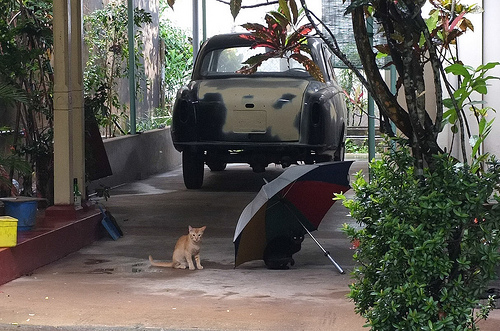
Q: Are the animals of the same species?
A: Yes, all the animals are cats.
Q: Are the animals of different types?
A: No, all the animals are cats.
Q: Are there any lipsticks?
A: No, there are no lipsticks.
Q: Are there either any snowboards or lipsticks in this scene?
A: No, there are no lipsticks or snowboards.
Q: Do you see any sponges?
A: No, there are no sponges.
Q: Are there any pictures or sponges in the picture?
A: No, there are no sponges or pictures.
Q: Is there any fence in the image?
A: No, there are no fences.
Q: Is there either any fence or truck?
A: No, there are no fences or trucks.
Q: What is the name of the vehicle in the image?
A: The vehicle is a car.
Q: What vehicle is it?
A: The vehicle is a car.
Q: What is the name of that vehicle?
A: This is a car.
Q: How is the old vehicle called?
A: The vehicle is a car.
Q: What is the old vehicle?
A: The vehicle is a car.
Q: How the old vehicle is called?
A: The vehicle is a car.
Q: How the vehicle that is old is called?
A: The vehicle is a car.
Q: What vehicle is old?
A: The vehicle is a car.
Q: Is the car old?
A: Yes, the car is old.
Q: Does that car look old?
A: Yes, the car is old.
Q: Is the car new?
A: No, the car is old.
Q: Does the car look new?
A: No, the car is old.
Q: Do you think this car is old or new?
A: The car is old.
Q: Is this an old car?
A: Yes, this is an old car.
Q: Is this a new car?
A: No, this is an old car.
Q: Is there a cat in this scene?
A: Yes, there is a cat.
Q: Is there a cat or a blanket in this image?
A: Yes, there is a cat.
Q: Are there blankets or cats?
A: Yes, there is a cat.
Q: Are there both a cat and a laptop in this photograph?
A: No, there is a cat but no laptops.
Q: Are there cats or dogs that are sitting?
A: Yes, the cat is sitting.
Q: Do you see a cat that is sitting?
A: Yes, there is a cat that is sitting.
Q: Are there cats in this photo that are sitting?
A: Yes, there is a cat that is sitting.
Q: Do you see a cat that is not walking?
A: Yes, there is a cat that is sitting .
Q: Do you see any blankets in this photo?
A: No, there are no blankets.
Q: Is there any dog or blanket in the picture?
A: No, there are no blankets or dogs.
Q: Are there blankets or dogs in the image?
A: No, there are no blankets or dogs.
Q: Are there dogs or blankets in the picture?
A: No, there are no blankets or dogs.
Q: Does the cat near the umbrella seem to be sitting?
A: Yes, the cat is sitting.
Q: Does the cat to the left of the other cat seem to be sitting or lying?
A: The cat is sitting.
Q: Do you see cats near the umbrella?
A: Yes, there is a cat near the umbrella.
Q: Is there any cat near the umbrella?
A: Yes, there is a cat near the umbrella.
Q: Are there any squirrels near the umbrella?
A: No, there is a cat near the umbrella.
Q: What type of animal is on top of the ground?
A: The animal is a cat.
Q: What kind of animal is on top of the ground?
A: The animal is a cat.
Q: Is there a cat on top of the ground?
A: Yes, there is a cat on top of the ground.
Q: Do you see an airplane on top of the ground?
A: No, there is a cat on top of the ground.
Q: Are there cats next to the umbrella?
A: Yes, there is a cat next to the umbrella.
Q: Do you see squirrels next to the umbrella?
A: No, there is a cat next to the umbrella.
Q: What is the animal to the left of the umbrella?
A: The animal is a cat.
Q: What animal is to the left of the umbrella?
A: The animal is a cat.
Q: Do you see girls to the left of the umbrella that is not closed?
A: No, there is a cat to the left of the umbrella.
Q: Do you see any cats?
A: Yes, there is a cat.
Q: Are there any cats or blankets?
A: Yes, there is a cat.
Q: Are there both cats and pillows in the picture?
A: No, there is a cat but no pillows.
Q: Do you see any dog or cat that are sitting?
A: Yes, the cat is sitting.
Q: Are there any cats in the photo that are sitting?
A: Yes, there is a cat that is sitting.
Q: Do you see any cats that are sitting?
A: Yes, there is a cat that is sitting.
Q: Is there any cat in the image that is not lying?
A: Yes, there is a cat that is sitting.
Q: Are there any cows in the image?
A: No, there are no cows.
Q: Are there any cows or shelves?
A: No, there are no cows or shelves.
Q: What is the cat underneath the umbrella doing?
A: The cat is sitting.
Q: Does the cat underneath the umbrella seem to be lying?
A: No, the cat is sitting.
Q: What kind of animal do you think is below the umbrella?
A: The animal is a cat.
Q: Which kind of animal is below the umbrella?
A: The animal is a cat.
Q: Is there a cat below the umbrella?
A: Yes, there is a cat below the umbrella.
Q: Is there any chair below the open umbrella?
A: No, there is a cat below the umbrella.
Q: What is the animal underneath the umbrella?
A: The animal is a cat.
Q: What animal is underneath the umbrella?
A: The animal is a cat.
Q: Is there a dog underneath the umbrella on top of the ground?
A: No, there is a cat underneath the umbrella.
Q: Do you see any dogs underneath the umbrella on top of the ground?
A: No, there is a cat underneath the umbrella.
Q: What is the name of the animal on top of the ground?
A: The animal is a cat.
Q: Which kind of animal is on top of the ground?
A: The animal is a cat.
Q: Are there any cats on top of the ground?
A: Yes, there is a cat on top of the ground.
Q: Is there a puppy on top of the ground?
A: No, there is a cat on top of the ground.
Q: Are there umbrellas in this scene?
A: Yes, there is an umbrella.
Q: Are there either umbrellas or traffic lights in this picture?
A: Yes, there is an umbrella.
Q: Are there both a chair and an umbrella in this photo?
A: No, there is an umbrella but no chairs.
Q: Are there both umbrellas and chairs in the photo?
A: No, there is an umbrella but no chairs.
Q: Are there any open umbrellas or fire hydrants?
A: Yes, there is an open umbrella.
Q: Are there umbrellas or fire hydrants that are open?
A: Yes, the umbrella is open.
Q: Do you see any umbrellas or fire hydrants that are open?
A: Yes, the umbrella is open.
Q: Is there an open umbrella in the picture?
A: Yes, there is an open umbrella.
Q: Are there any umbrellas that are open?
A: Yes, there is an umbrella that is open.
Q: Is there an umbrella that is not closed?
A: Yes, there is a open umbrella.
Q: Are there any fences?
A: No, there are no fences.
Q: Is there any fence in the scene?
A: No, there are no fences.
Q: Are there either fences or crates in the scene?
A: No, there are no fences or crates.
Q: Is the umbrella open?
A: Yes, the umbrella is open.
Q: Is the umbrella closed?
A: No, the umbrella is open.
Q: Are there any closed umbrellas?
A: No, there is an umbrella but it is open.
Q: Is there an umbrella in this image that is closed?
A: No, there is an umbrella but it is open.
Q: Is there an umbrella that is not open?
A: No, there is an umbrella but it is open.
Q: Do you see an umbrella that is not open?
A: No, there is an umbrella but it is open.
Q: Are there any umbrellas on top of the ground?
A: Yes, there is an umbrella on top of the ground.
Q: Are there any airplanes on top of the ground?
A: No, there is an umbrella on top of the ground.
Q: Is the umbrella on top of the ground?
A: Yes, the umbrella is on top of the ground.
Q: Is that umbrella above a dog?
A: No, the umbrella is above the cat.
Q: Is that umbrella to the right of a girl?
A: No, the umbrella is to the right of the cat.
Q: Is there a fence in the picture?
A: No, there are no fences.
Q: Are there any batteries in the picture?
A: No, there are no batteries.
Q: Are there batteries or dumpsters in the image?
A: No, there are no batteries or dumpsters.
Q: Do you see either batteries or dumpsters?
A: No, there are no batteries or dumpsters.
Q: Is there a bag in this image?
A: No, there are no bags.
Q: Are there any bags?
A: No, there are no bags.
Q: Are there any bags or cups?
A: No, there are no bags or cups.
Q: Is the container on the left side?
A: Yes, the container is on the left of the image.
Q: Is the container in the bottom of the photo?
A: Yes, the container is in the bottom of the image.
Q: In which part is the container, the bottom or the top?
A: The container is in the bottom of the image.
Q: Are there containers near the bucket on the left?
A: Yes, there is a container near the bucket.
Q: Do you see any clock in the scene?
A: No, there are no clocks.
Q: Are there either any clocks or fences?
A: No, there are no clocks or fences.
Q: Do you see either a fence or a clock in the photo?
A: No, there are no clocks or fences.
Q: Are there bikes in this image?
A: No, there are no bikes.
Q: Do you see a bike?
A: No, there are no bikes.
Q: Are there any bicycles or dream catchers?
A: No, there are no bicycles or dream catchers.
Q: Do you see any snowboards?
A: No, there are no snowboards.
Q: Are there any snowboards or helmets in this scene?
A: No, there are no snowboards or helmets.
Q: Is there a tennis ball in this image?
A: No, there are no tennis balls.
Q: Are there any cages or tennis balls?
A: No, there are no tennis balls or cages.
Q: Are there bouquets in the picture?
A: No, there are no bouquets.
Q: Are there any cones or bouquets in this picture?
A: No, there are no bouquets or cones.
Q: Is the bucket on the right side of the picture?
A: No, the bucket is on the left of the image.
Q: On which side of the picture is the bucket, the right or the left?
A: The bucket is on the left of the image.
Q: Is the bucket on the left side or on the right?
A: The bucket is on the left of the image.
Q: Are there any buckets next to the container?
A: Yes, there is a bucket next to the container.